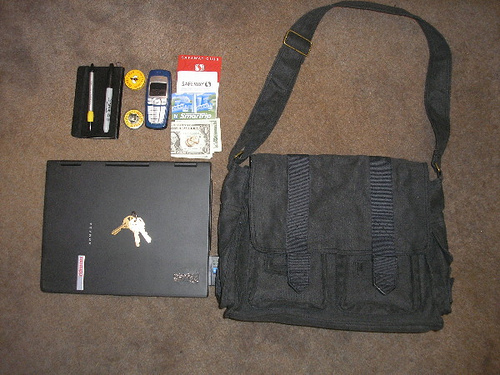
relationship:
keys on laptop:
[108, 210, 153, 249] [34, 150, 217, 303]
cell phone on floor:
[142, 69, 170, 129] [3, 1, 497, 373]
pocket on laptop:
[237, 234, 309, 295] [37, 158, 215, 299]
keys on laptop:
[108, 210, 153, 249] [37, 158, 215, 299]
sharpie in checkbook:
[101, 62, 115, 134] [69, 62, 125, 140]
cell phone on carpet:
[146, 70, 173, 131] [4, 5, 499, 370]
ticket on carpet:
[172, 50, 222, 118] [4, 5, 499, 370]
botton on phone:
[153, 97, 162, 106] [145, 67, 167, 129]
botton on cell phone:
[153, 97, 162, 106] [143, 65, 170, 131]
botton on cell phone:
[149, 117, 154, 121] [143, 65, 170, 131]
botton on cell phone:
[153, 97, 162, 106] [145, 63, 172, 129]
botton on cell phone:
[153, 97, 162, 106] [143, 67, 171, 127]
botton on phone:
[153, 97, 162, 106] [142, 64, 171, 128]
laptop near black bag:
[37, 157, 211, 299] [213, 1, 461, 335]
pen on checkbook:
[81, 56, 103, 138] [69, 61, 125, 143]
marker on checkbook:
[98, 59, 122, 137] [69, 61, 125, 143]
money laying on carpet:
[163, 112, 225, 167] [327, 65, 367, 102]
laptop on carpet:
[37, 157, 211, 299] [4, 5, 499, 370]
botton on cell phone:
[153, 97, 162, 106] [142, 69, 170, 129]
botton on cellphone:
[153, 97, 162, 106] [143, 69, 169, 130]